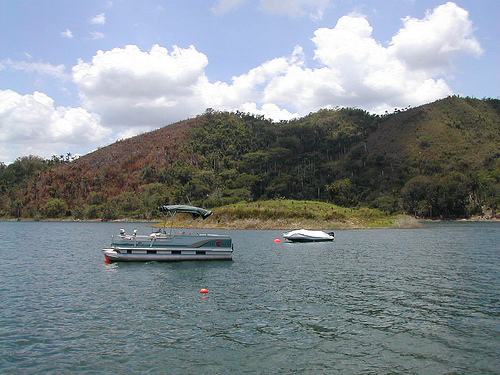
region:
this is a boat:
[103, 199, 233, 267]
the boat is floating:
[105, 200, 227, 261]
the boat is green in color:
[106, 200, 229, 268]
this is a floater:
[281, 216, 336, 245]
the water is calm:
[292, 270, 418, 371]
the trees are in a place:
[219, 125, 329, 187]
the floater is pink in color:
[199, 286, 209, 293]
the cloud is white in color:
[91, 54, 191, 108]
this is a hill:
[390, 95, 490, 158]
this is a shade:
[159, 195, 209, 218]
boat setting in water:
[82, 176, 259, 288]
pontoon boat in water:
[102, 196, 269, 287]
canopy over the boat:
[117, 199, 264, 281]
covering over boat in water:
[263, 214, 355, 252]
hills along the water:
[187, 109, 415, 252]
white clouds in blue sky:
[53, 1, 246, 135]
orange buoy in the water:
[163, 261, 258, 323]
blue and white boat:
[110, 227, 266, 279]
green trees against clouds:
[199, 89, 295, 168]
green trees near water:
[384, 159, 488, 259]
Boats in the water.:
[93, 202, 373, 299]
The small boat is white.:
[278, 216, 358, 251]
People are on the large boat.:
[97, 204, 174, 248]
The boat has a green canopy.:
[148, 196, 227, 230]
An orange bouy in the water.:
[188, 281, 215, 304]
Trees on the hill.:
[98, 115, 482, 232]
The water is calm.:
[268, 263, 438, 365]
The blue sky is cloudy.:
[41, 24, 424, 124]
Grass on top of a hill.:
[236, 191, 364, 227]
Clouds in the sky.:
[86, 62, 359, 123]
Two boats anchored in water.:
[94, 188, 345, 275]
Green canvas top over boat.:
[152, 201, 221, 223]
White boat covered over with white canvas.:
[284, 223, 329, 242]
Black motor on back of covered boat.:
[327, 228, 342, 240]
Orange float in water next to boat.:
[184, 276, 222, 305]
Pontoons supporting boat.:
[102, 248, 242, 266]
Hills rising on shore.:
[103, 92, 496, 208]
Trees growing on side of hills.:
[190, 103, 368, 199]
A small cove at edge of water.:
[415, 210, 495, 234]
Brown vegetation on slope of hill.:
[57, 126, 196, 194]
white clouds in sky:
[80, 26, 180, 118]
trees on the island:
[198, 127, 288, 181]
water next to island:
[310, 258, 401, 320]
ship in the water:
[107, 218, 239, 276]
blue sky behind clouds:
[190, 10, 260, 70]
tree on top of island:
[51, 147, 81, 169]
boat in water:
[268, 216, 348, 263]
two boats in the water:
[88, 203, 365, 306]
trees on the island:
[391, 168, 483, 217]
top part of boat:
[153, 189, 216, 234]